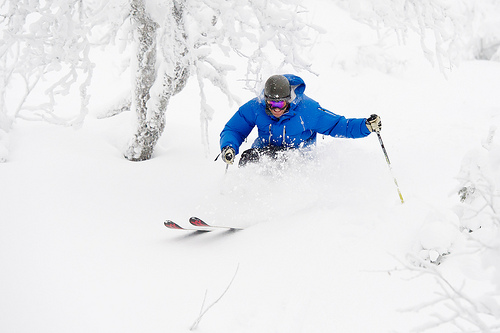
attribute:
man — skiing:
[218, 73, 381, 168]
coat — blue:
[219, 73, 371, 151]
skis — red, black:
[161, 216, 243, 237]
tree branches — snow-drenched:
[30, 31, 100, 103]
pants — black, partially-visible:
[239, 142, 294, 164]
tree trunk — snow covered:
[120, 0, 217, 162]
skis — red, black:
[162, 215, 246, 232]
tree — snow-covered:
[5, 4, 51, 121]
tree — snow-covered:
[61, 3, 106, 125]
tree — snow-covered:
[120, 6, 200, 162]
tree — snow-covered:
[396, 3, 448, 73]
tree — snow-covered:
[469, 7, 499, 53]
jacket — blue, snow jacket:
[213, 115, 363, 149]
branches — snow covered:
[394, 250, 498, 331]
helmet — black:
[264, 75, 290, 98]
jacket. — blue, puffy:
[174, 42, 385, 209]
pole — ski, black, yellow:
[322, 80, 456, 261]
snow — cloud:
[6, 124, 493, 331]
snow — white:
[0, 60, 498, 331]